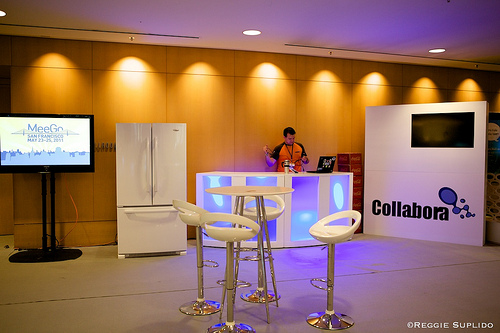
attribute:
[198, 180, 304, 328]
table — high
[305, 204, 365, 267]
chair — white, ultra modern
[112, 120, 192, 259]
refrigerator — double door, white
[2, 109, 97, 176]
tv — flat screen, black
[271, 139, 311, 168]
shirt — orange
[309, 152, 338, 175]
laptop — black